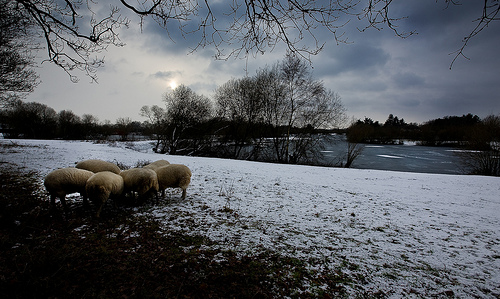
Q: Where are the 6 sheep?
A: Huddled together.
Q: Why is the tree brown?
A: Winter.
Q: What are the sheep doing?
A: Eating.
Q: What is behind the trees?
A: Frozen pond.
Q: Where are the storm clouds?
A: Above the house.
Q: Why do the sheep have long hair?
A: To keep warm.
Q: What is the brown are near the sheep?
A: Brown dirt, mud.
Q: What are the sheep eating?
A: Grass, hay.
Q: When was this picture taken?
A: Daytime.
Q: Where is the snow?
A: On the ground.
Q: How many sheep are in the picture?
A: Six.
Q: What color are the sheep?
A: White.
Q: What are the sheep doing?
A: Eating.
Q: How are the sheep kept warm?
A: Wool.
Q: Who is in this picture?
A: No one.